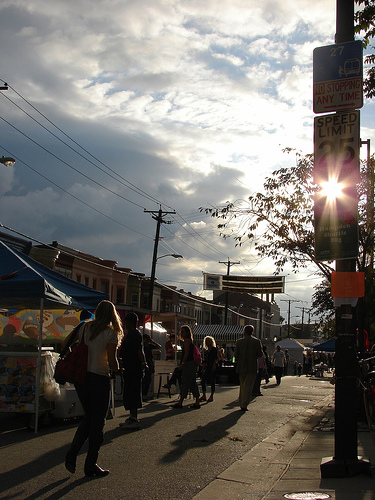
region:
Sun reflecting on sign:
[311, 155, 361, 260]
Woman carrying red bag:
[51, 297, 124, 482]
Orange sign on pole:
[325, 265, 371, 310]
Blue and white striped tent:
[190, 322, 252, 351]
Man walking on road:
[227, 323, 266, 415]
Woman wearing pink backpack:
[173, 320, 202, 413]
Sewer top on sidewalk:
[270, 479, 337, 498]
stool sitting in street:
[153, 366, 175, 402]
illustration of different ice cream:
[0, 310, 84, 346]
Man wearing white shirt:
[268, 340, 290, 388]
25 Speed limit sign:
[307, 110, 361, 187]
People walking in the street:
[61, 296, 309, 477]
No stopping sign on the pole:
[298, 42, 367, 114]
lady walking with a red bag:
[50, 286, 118, 481]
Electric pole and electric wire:
[1, 67, 240, 257]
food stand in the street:
[1, 241, 122, 437]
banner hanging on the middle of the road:
[192, 258, 308, 293]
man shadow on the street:
[154, 403, 267, 478]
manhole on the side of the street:
[276, 484, 331, 499]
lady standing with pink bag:
[167, 316, 210, 416]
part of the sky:
[239, 43, 263, 66]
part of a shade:
[163, 431, 205, 470]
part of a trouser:
[85, 416, 111, 449]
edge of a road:
[258, 448, 282, 482]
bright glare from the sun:
[287, 145, 366, 246]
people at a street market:
[5, 272, 365, 489]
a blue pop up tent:
[4, 226, 119, 439]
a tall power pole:
[127, 190, 191, 329]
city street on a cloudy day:
[7, 139, 367, 498]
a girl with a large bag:
[36, 282, 131, 483]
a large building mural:
[4, 298, 105, 350]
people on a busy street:
[5, 228, 370, 498]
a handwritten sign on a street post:
[315, 267, 370, 314]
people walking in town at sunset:
[5, 233, 370, 496]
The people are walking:
[23, 304, 274, 454]